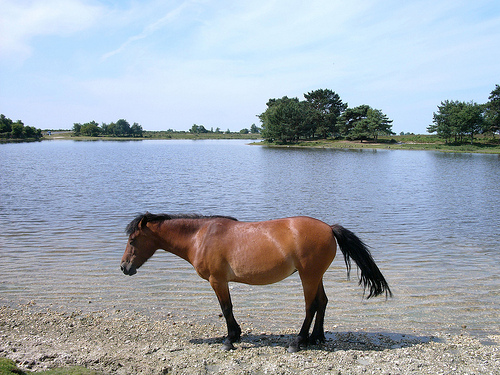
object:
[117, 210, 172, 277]
head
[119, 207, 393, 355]
horse standing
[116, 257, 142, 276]
snout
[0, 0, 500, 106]
clouds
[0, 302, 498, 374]
stones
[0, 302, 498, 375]
ground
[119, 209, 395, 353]
horse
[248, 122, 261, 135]
trees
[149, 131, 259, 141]
grass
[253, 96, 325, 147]
trees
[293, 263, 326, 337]
legs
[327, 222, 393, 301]
tail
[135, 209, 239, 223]
mane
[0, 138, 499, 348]
water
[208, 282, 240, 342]
front leg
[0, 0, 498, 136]
sky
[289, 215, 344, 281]
rear